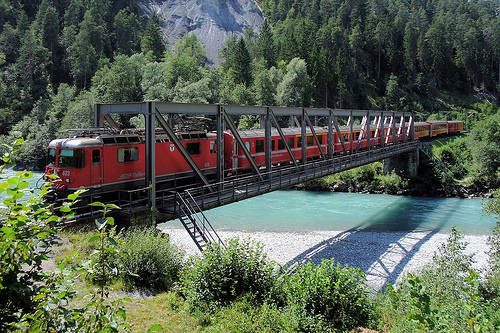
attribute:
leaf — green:
[88, 199, 125, 211]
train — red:
[89, 122, 318, 198]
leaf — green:
[105, 202, 122, 209]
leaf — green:
[86, 199, 102, 206]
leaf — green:
[17, 180, 29, 190]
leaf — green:
[93, 216, 108, 230]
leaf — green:
[105, 213, 116, 228]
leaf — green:
[42, 11, 50, 19]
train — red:
[37, 104, 477, 212]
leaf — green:
[366, 17, 394, 46]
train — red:
[53, 101, 419, 208]